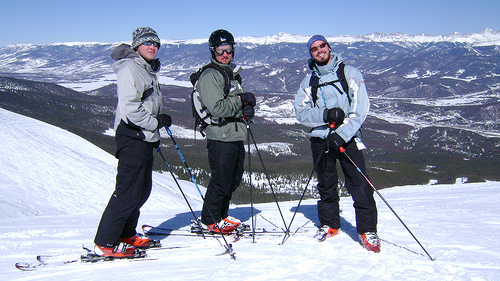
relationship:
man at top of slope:
[291, 33, 390, 255] [1, 108, 500, 278]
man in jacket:
[188, 29, 265, 234] [191, 57, 253, 142]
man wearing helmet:
[188, 29, 265, 234] [205, 27, 234, 45]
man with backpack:
[188, 29, 265, 234] [189, 67, 234, 128]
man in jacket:
[291, 33, 391, 257] [288, 54, 372, 143]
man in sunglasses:
[291, 33, 391, 257] [309, 42, 328, 51]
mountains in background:
[3, 25, 499, 94] [445, 37, 496, 43]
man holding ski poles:
[291, 33, 391, 257] [275, 118, 435, 258]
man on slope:
[291, 33, 390, 255] [1, 108, 500, 278]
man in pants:
[291, 33, 390, 255] [200, 139, 253, 222]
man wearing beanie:
[291, 33, 391, 257] [306, 30, 331, 47]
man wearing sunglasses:
[291, 33, 391, 257] [309, 42, 328, 51]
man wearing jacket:
[291, 33, 391, 257] [288, 54, 372, 143]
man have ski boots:
[291, 33, 390, 255] [89, 228, 154, 256]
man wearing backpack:
[291, 33, 391, 257] [189, 67, 234, 128]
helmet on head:
[205, 27, 234, 45] [207, 27, 238, 68]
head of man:
[207, 27, 238, 68] [188, 29, 265, 234]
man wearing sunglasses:
[92, 20, 178, 253] [138, 41, 164, 46]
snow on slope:
[136, 250, 443, 271] [1, 108, 500, 278]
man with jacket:
[188, 29, 265, 234] [191, 57, 253, 142]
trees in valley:
[260, 173, 307, 190] [2, 73, 498, 190]